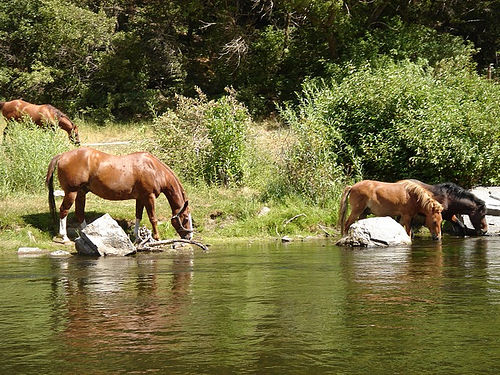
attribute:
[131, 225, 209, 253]
branches — dead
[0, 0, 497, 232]
forest — dense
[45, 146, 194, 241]
horse — brown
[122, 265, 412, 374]
water lake — fresh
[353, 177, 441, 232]
horse — brown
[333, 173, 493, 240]
horses — drinking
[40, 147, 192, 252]
horse — brown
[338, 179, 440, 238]
horse — brown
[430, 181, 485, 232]
horse — brown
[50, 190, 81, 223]
leg — brown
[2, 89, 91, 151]
horse — brown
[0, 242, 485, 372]
water — ripples